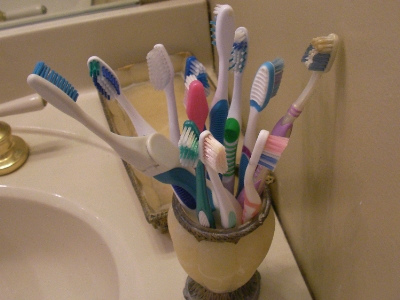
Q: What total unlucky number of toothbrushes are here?
A: 13.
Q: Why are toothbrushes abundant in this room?
A: Lots of people need them.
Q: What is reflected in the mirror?
A: The faucet handle.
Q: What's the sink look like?
A: The sink is white.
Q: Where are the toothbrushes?
A: In the toothbrush holder.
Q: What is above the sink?
A: A mirror.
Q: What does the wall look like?
A: The wall is beige.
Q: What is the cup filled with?
A: Toothbrushes.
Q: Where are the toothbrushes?
A: In a container.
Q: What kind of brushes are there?
A: Multiple and varied kind.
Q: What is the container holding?
A: Different colored toothbrushes.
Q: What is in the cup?
A: Multiple toothbrushes.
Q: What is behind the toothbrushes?
A: Tan and gold soap dish.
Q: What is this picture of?
A: Toothbrushes.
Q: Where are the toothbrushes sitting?
A: On the sink.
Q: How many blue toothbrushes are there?
A: 5.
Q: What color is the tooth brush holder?
A: Cream and brown.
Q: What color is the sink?
A: White.